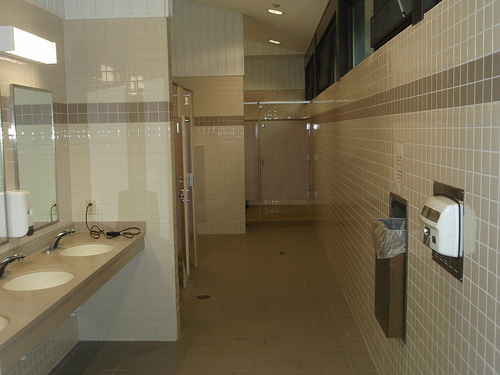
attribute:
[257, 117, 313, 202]
door — clouded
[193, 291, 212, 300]
drain — round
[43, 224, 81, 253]
faucet — silver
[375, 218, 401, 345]
trash can — silver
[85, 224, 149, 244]
electrical cord — black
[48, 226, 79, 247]
faucet — silver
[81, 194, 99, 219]
outlet — power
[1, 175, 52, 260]
soap dispenser — white and plastic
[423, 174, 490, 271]
hand dryer — hot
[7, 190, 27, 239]
paper towels — white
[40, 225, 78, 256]
faucet — chrome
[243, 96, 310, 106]
pipe — silver, support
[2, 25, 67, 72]
light — fluorescent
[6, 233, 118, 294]
sinks — multiple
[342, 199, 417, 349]
receptacle — stainless steel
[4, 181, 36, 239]
soap dispenser — white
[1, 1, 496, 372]
bathroom — tan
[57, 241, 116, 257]
sink — white, round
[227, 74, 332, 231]
stall — door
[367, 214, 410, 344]
bag — plastic